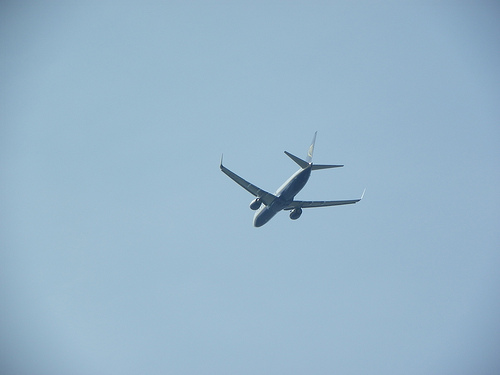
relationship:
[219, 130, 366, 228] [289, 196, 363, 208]
airplane has right wing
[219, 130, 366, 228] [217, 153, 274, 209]
airplane has left wing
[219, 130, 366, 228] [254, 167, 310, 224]
airplane has bottom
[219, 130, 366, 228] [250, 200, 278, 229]
airplane has front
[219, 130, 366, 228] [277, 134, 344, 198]
airplane has back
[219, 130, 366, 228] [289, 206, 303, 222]
airplane has engine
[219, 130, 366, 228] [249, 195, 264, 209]
airplane has engine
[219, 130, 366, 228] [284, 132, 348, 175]
airplane has tip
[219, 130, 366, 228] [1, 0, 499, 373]
airplane in sky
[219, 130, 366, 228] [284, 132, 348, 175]
airplane has tail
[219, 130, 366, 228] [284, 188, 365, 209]
airplane has right wing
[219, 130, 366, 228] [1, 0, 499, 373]
airplane flying in sky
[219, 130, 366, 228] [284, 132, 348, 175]
airplane has a tail